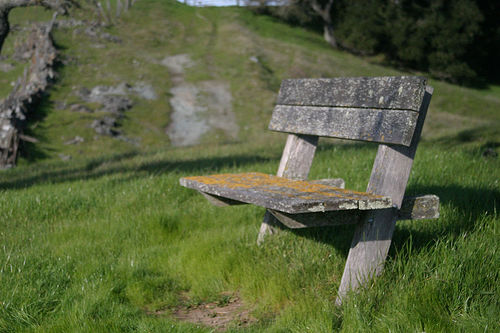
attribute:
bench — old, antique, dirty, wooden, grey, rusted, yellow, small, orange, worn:
[181, 71, 443, 309]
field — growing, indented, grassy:
[0, 1, 499, 329]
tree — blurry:
[305, 2, 341, 53]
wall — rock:
[11, 22, 80, 189]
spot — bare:
[163, 287, 261, 328]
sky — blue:
[173, 1, 296, 14]